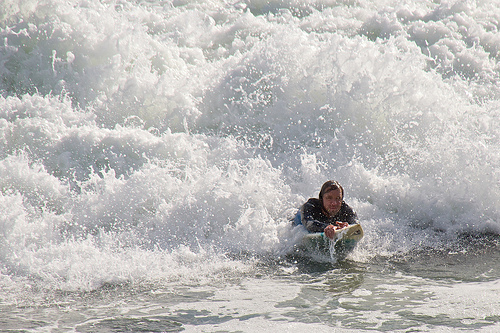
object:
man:
[287, 178, 361, 238]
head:
[318, 180, 345, 218]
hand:
[323, 223, 340, 239]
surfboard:
[307, 222, 365, 265]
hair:
[318, 179, 345, 217]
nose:
[330, 199, 338, 207]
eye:
[324, 196, 334, 200]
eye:
[333, 197, 342, 202]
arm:
[297, 203, 329, 234]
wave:
[1, 5, 499, 288]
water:
[6, 231, 500, 332]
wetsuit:
[290, 197, 361, 233]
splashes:
[32, 233, 246, 296]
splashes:
[365, 218, 454, 264]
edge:
[305, 223, 364, 239]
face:
[321, 188, 344, 215]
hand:
[334, 219, 351, 230]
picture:
[0, 2, 499, 331]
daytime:
[0, 1, 499, 331]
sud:
[173, 271, 303, 333]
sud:
[352, 274, 499, 332]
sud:
[12, 289, 160, 333]